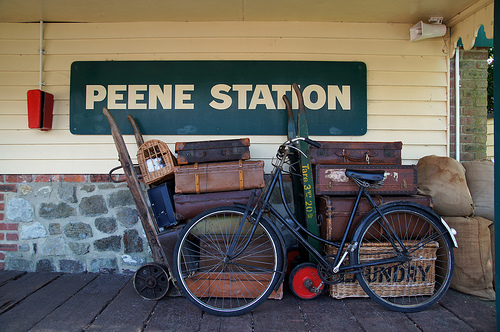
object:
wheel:
[132, 263, 171, 302]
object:
[24, 89, 54, 133]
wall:
[0, 24, 453, 174]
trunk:
[306, 140, 404, 165]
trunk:
[314, 164, 416, 194]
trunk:
[170, 159, 265, 195]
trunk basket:
[326, 239, 440, 300]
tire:
[170, 205, 285, 318]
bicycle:
[167, 138, 460, 317]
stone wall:
[0, 172, 298, 275]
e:
[105, 82, 125, 110]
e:
[126, 83, 148, 110]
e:
[173, 83, 196, 111]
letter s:
[207, 83, 235, 111]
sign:
[68, 60, 366, 136]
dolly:
[100, 106, 188, 301]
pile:
[134, 137, 290, 301]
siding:
[0, 54, 448, 74]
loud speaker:
[407, 22, 447, 43]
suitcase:
[173, 137, 251, 166]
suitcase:
[171, 187, 265, 222]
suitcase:
[323, 195, 430, 244]